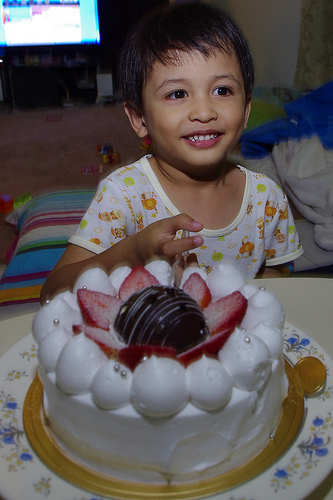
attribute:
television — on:
[1, 3, 111, 56]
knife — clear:
[170, 226, 203, 304]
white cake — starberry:
[76, 249, 293, 468]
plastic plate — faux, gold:
[25, 357, 320, 498]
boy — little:
[38, 5, 301, 304]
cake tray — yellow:
[15, 263, 325, 498]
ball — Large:
[114, 283, 207, 344]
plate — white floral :
[2, 294, 332, 496]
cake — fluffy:
[17, 245, 328, 440]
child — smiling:
[144, 32, 249, 170]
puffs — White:
[28, 256, 290, 425]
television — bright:
[1, 1, 101, 46]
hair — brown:
[117, 0, 254, 115]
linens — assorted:
[242, 145, 331, 270]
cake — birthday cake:
[23, 259, 312, 494]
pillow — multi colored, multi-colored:
[0, 189, 98, 308]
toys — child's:
[77, 138, 125, 180]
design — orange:
[141, 197, 156, 210]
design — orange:
[265, 203, 277, 217]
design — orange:
[239, 239, 255, 255]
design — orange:
[97, 208, 124, 222]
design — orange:
[110, 225, 127, 241]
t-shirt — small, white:
[63, 153, 306, 283]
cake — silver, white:
[33, 257, 292, 490]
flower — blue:
[271, 462, 295, 480]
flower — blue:
[298, 432, 329, 461]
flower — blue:
[310, 413, 323, 427]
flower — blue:
[5, 393, 19, 410]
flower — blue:
[19, 447, 35, 462]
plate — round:
[0, 316, 331, 497]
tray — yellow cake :
[278, 465, 329, 492]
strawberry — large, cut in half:
[201, 285, 246, 331]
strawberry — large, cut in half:
[77, 287, 122, 326]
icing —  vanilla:
[93, 410, 237, 483]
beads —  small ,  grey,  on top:
[112, 364, 127, 377]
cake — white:
[19, 246, 287, 454]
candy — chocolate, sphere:
[106, 273, 207, 347]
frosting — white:
[30, 292, 289, 466]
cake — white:
[36, 239, 285, 495]